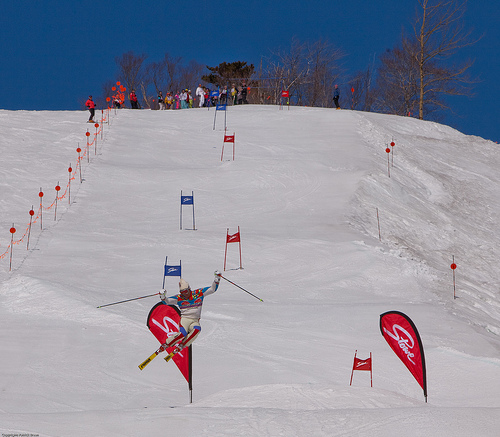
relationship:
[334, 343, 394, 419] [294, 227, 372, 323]
flag in snow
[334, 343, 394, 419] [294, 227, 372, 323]
flag on snow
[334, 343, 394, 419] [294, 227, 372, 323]
flag with snow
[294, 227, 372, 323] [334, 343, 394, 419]
snow with flag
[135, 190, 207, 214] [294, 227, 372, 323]
marker in snow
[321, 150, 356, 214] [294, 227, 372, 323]
writing in snow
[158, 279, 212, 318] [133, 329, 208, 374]
person on skis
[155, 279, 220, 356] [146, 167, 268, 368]
person on slope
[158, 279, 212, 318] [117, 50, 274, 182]
person on hill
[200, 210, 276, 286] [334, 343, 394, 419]
obstacle with flag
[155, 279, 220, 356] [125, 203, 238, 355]
person has jumped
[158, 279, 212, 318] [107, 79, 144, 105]
person in orange